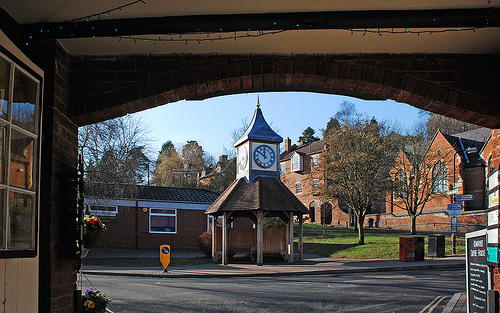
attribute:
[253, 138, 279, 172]
clock — white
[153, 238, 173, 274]
sign — orange, yellow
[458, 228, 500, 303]
sign — black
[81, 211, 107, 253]
flowers — hanging, red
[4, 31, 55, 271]
window — paned, pane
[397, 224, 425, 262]
box — brown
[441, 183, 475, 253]
signs — blue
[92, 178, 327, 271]
building — one story, brick, large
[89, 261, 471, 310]
road — black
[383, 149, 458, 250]
tree — bare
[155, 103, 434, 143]
sky — blue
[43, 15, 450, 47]
lights — blue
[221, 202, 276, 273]
archway — brick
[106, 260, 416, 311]
street — paved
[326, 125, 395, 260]
tree — green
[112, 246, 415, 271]
sidewalk — paved, brick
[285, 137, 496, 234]
building — large